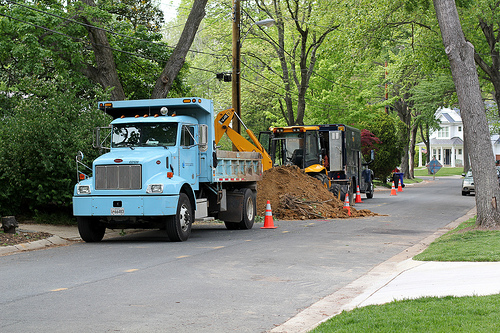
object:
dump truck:
[72, 95, 264, 242]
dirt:
[254, 164, 388, 221]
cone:
[257, 199, 278, 229]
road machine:
[215, 107, 376, 200]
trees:
[0, 0, 200, 226]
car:
[460, 170, 475, 196]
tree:
[359, 127, 383, 157]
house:
[426, 105, 499, 168]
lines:
[174, 254, 188, 259]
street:
[0, 174, 474, 331]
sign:
[424, 157, 443, 176]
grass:
[301, 292, 499, 332]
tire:
[163, 193, 195, 242]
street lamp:
[239, 18, 275, 39]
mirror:
[197, 122, 209, 146]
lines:
[2, 1, 357, 110]